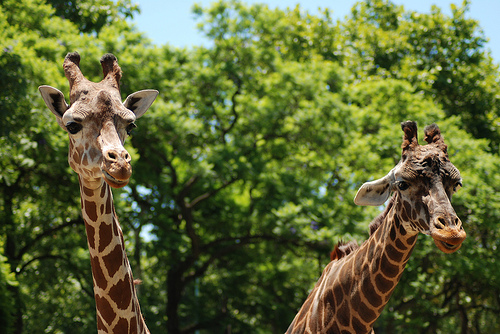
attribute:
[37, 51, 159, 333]
giraffe — spotted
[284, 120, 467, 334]
giraffe — spotted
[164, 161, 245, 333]
tree — tall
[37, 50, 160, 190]
head — angular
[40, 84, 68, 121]
ear — black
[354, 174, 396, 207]
ear — white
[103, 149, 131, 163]
nose — skanted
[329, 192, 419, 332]
neck — angled, tubeular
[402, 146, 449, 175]
forehead — wrinkled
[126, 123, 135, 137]
eye — black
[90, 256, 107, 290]
spot — brown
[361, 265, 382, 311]
spot — brown